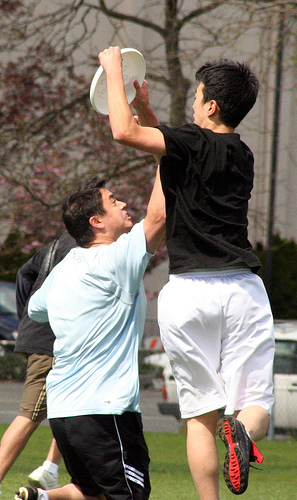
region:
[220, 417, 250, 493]
A black and red shoe on the right foot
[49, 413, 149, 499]
The man is wearing black pants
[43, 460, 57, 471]
The man is wearing socks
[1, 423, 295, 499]
Grass beneath the men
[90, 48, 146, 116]
A white frisbee in the man's hands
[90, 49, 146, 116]
The frisbee is circular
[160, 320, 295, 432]
A car parked on the street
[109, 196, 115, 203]
The right eye of the man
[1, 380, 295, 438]
The street beneath the car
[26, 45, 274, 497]
two men playing frisbee in a park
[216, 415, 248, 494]
black and red sole of a shoe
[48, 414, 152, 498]
black shots with white lines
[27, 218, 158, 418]
man wearing a white T-shirt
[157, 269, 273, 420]
man wearing white shorts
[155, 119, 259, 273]
man wearing a black shirt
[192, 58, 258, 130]
man with short black hair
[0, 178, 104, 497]
a man running in a park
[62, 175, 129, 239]
man with short brown hair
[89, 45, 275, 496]
man holding a white frisbee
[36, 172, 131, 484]
this is a man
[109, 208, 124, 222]
the man is light skinned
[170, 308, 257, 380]
this is a short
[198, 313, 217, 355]
the short is white in color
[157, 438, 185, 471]
the grass is green in color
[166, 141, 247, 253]
this is a t shirt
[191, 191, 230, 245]
the t shirt is black in color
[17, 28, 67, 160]
this is a tree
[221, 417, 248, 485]
this is a shoe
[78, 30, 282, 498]
Man catching frisbee disk.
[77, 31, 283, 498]
Man wearing black shirt catching frisbee disk.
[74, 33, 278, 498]
Man with white pants catching frisbee disk.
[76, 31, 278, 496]
Man holding frisbee disk.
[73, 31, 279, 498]
Flying disk being grasped.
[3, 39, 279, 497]
Two men contesting for flying disk.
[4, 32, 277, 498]
Two men competing for frisbee disk.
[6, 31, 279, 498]
Man in blue shirt challenging for frisbee disk.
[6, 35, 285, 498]
Man in black and white pants challenging for flying disk.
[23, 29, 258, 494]
people playing game of frisbee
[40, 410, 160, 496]
shorts on a person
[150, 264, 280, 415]
shorts on the person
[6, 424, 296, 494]
lawn people play on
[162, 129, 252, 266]
shirt on the person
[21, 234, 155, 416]
shirt on the person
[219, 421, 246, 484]
sole of the shoe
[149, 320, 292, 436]
vehicle on side of street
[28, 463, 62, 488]
shoe on the person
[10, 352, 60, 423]
shorts on the person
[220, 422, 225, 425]
red nub on the bottom of the cleat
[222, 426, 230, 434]
red nub on the bottom of the cleat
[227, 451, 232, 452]
red nub on the bottom of the cleat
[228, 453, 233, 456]
red nub on the bottom of the cleat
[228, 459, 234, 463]
red nub on the bottom of the cleat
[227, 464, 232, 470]
red nub on the bottom of the cleat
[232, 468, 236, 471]
red nub on the bottom of the cleat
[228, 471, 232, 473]
red nub on the bottom of the cleat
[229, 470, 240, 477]
red nub on the bottom of the cleat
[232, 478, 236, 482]
red nub on the bottom of the cleat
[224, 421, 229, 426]
red bump on shoe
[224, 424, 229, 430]
red bump on shoe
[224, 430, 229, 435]
red bump on shoe